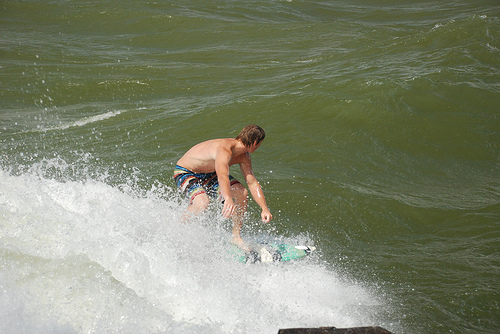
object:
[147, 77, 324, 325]
man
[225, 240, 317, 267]
surfboard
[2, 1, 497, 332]
ocean waves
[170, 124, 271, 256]
surfer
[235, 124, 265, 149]
hair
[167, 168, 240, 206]
shorts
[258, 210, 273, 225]
hand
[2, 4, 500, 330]
water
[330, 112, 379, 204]
green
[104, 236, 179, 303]
white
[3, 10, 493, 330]
ocean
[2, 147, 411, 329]
wave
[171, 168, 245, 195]
swimming trunks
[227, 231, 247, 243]
foot